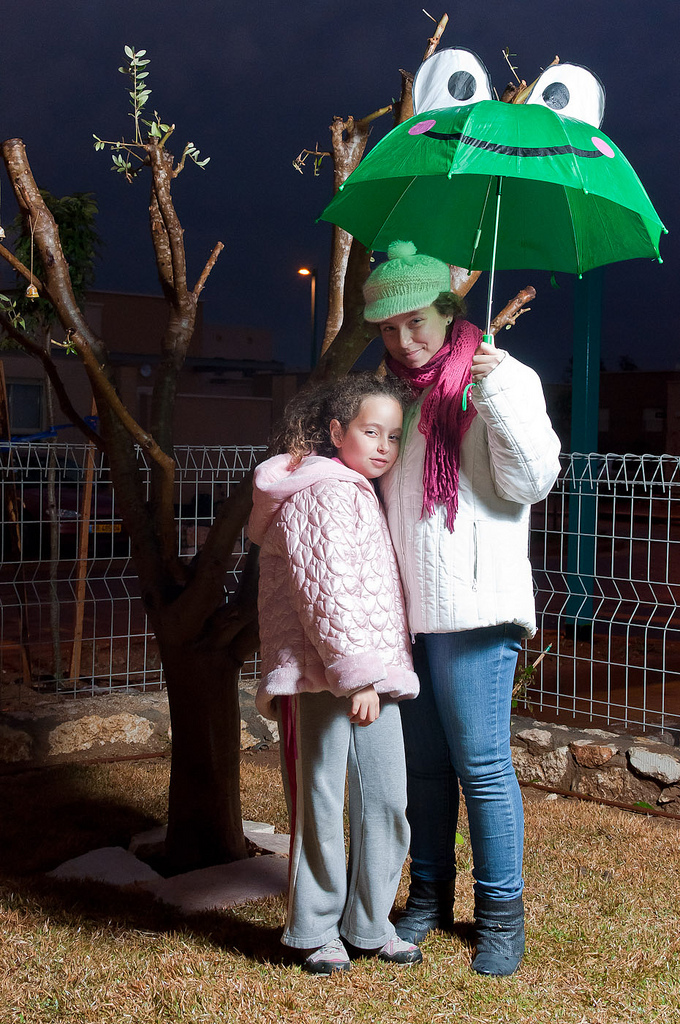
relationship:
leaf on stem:
[121, 43, 131, 66] [130, 60, 146, 147]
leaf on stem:
[132, 45, 150, 57] [131, 65, 138, 133]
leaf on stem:
[135, 56, 150, 65] [127, 58, 145, 138]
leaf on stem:
[132, 69, 147, 77] [131, 64, 138, 140]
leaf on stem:
[134, 90, 149, 103] [126, 64, 145, 144]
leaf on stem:
[89, 136, 100, 145] [99, 128, 147, 150]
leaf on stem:
[108, 150, 122, 167] [115, 139, 134, 160]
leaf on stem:
[198, 155, 209, 168] [172, 137, 197, 177]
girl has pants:
[248, 382, 417, 972] [273, 693, 411, 949]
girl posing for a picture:
[248, 371, 423, 974] [1, 1, 631, 1019]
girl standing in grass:
[248, 371, 423, 974] [529, 798, 660, 1020]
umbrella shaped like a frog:
[313, 46, 663, 372] [412, 46, 614, 165]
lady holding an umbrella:
[362, 236, 562, 976] [325, 46, 660, 280]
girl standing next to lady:
[248, 371, 423, 974] [362, 236, 562, 976]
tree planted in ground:
[2, 10, 588, 862] [1, 902, 286, 1021]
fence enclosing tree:
[4, 434, 678, 744] [3, 45, 261, 869]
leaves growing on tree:
[85, 42, 217, 182] [1, 40, 324, 356]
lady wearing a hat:
[344, 235, 569, 981] [363, 231, 456, 323]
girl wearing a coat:
[248, 371, 423, 974] [248, 452, 417, 696]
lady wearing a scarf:
[344, 235, 569, 981] [381, 295, 514, 609]